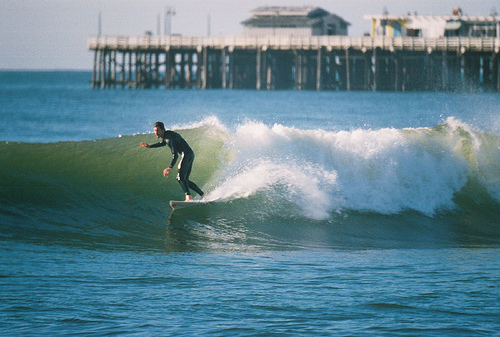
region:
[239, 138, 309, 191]
a splash in the water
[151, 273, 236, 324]
the water is blue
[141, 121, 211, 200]
a man surfing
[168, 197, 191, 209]
a surfboard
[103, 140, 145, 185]
a wave in the water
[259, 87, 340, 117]
the water is blue and clear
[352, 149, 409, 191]
the white water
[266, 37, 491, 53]
the pier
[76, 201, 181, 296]
the ocean water is blue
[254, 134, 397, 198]
a splash of water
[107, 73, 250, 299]
he is surfing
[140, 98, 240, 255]
he is riding a wave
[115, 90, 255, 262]
he is riding a surfboard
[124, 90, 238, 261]
he is standing on a surfboard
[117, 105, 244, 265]
he is on a wave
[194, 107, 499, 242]
the wave is crashing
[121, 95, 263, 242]
the man is wearing a black wetsuit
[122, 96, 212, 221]
a surfer in a black wetsuit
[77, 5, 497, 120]
this is a pier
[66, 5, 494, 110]
the pier has wooden beams and posts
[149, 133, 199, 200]
the wetsuit of a surfer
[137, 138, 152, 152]
the hand of a surfer surfing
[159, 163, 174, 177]
the hand of a surfer surfing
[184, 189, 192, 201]
the foot of a surfer surfing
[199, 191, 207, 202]
the foot of a surfer surfing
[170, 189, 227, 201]
the surfboard of a surfer surfing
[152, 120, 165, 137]
the head of a surfer surfing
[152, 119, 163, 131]
the hair of a surfer surfing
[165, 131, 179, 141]
the shoulder of a surfer surfing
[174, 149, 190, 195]
the leg of a surfer surfing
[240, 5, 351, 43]
House on the boardwalk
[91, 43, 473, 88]
Wooden poles holding up the boardwalk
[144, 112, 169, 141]
man with brown hair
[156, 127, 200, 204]
man wearing a wetsuit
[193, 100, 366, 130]
water spraying into the air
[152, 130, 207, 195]
man wearing a black wet suit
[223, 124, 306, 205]
Wave crashing in to the ocean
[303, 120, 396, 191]
Wave crashing in to the ocean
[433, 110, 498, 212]
Wave crashing in to the ocean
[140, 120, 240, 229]
A man on a surfboard.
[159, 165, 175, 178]
The mans right hand.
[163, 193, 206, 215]
The white surfboard.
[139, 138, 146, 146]
The mans right hand.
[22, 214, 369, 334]
The ocean.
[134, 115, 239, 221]
A man surfing.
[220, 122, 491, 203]
A large white water wave.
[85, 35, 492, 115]
A long dock built from wood.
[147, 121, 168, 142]
The mans head.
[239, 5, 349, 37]
Small property on the pier.